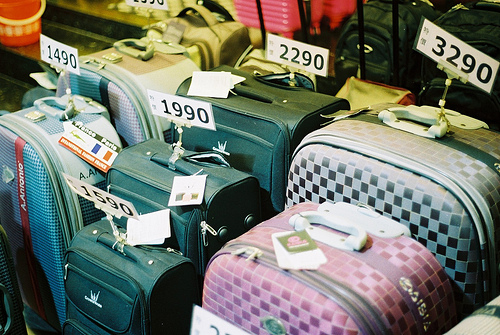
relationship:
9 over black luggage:
[297, 48, 313, 73] [181, 56, 333, 194]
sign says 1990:
[146, 92, 220, 131] [157, 76, 216, 161]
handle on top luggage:
[290, 208, 370, 250] [278, 199, 429, 314]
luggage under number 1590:
[199, 200, 461, 335] [62, 172, 136, 219]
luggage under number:
[199, 200, 461, 335] [410, 14, 495, 104]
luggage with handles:
[206, 200, 451, 329] [281, 205, 381, 260]